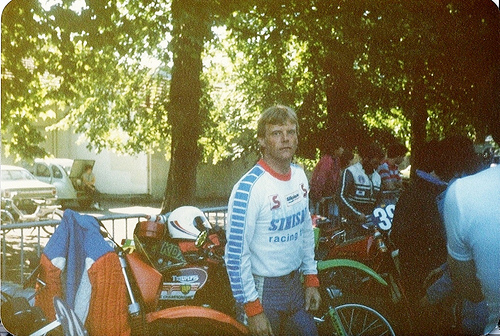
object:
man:
[222, 105, 322, 335]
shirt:
[227, 161, 321, 316]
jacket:
[38, 211, 128, 335]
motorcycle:
[0, 208, 225, 336]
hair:
[256, 105, 299, 136]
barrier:
[1, 199, 345, 307]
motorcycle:
[136, 211, 231, 262]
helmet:
[167, 205, 214, 241]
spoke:
[348, 310, 354, 336]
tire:
[314, 301, 402, 335]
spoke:
[361, 312, 368, 334]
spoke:
[376, 326, 394, 335]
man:
[341, 144, 384, 230]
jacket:
[340, 165, 382, 234]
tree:
[156, 0, 234, 212]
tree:
[300, 0, 359, 163]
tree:
[403, 0, 437, 172]